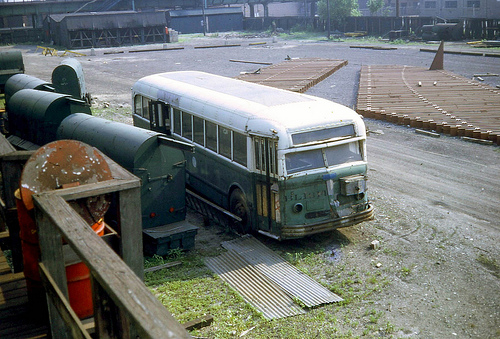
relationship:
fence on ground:
[196, 251, 306, 336] [310, 225, 398, 335]